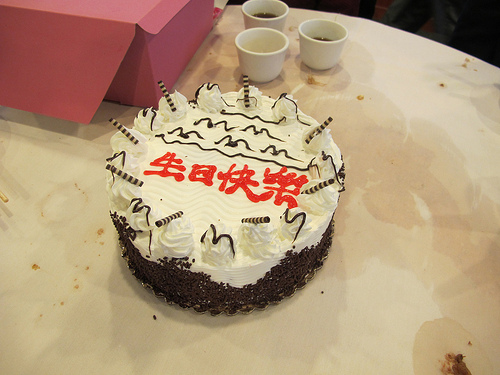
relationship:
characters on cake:
[144, 152, 310, 209] [101, 76, 347, 317]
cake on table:
[101, 76, 347, 317] [3, 0, 498, 373]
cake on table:
[101, 76, 347, 317] [1, 71, 498, 375]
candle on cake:
[127, 197, 208, 234] [74, 80, 397, 290]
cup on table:
[297, 11, 356, 71] [3, 0, 498, 373]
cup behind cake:
[234, 27, 287, 83] [82, 67, 358, 324]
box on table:
[0, 1, 214, 126] [347, 19, 498, 244]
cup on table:
[242, 0, 289, 33] [3, 0, 498, 373]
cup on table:
[297, 19, 349, 71] [402, 25, 459, 106]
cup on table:
[236, 25, 288, 83] [402, 25, 459, 106]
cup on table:
[242, 0, 289, 34] [402, 25, 459, 106]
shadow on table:
[107, 234, 349, 363] [3, 0, 498, 373]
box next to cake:
[0, 1, 214, 126] [101, 76, 347, 317]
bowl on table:
[238, 34, 286, 79] [320, 168, 438, 364]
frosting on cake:
[141, 150, 309, 211] [101, 76, 347, 317]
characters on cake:
[146, 146, 325, 211] [103, 90, 347, 294]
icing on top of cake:
[168, 112, 302, 167] [101, 76, 347, 317]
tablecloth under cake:
[0, 3, 500, 373] [101, 76, 347, 317]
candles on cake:
[95, 44, 353, 273] [101, 76, 347, 317]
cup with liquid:
[297, 19, 349, 71] [310, 33, 339, 42]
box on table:
[46, 20, 141, 110] [3, 0, 498, 373]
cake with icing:
[101, 76, 347, 317] [107, 74, 345, 286]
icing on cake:
[191, 165, 293, 235] [85, 115, 380, 315]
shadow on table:
[0, 0, 500, 374] [3, 0, 498, 373]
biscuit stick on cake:
[155, 211, 183, 227] [101, 76, 347, 317]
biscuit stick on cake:
[105, 164, 144, 187] [101, 76, 347, 317]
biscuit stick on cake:
[109, 117, 140, 144] [101, 76, 347, 317]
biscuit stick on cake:
[158, 80, 177, 112] [101, 76, 347, 317]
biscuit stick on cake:
[242, 75, 249, 107] [101, 76, 347, 317]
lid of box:
[1, 0, 227, 141] [0, 0, 231, 130]